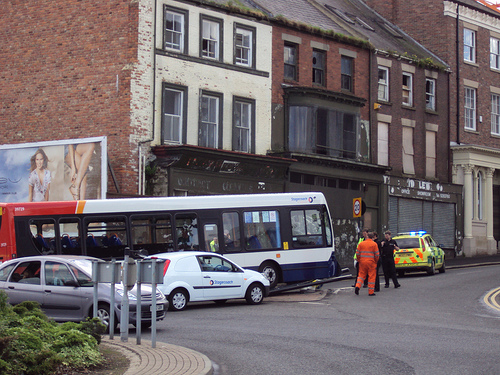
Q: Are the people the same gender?
A: No, they are both male and female.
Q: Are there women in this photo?
A: Yes, there is a woman.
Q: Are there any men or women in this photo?
A: Yes, there is a woman.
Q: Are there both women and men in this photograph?
A: Yes, there are both a woman and a man.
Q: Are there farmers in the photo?
A: No, there are no farmers.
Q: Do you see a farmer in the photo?
A: No, there are no farmers.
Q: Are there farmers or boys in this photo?
A: No, there are no farmers or boys.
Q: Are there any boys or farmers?
A: No, there are no farmers or boys.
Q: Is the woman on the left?
A: Yes, the woman is on the left of the image.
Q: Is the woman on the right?
A: No, the woman is on the left of the image.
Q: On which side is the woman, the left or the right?
A: The woman is on the left of the image.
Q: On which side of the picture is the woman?
A: The woman is on the left of the image.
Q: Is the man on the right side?
A: Yes, the man is on the right of the image.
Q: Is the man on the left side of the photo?
A: No, the man is on the right of the image.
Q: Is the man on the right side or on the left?
A: The man is on the right of the image.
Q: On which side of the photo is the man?
A: The man is on the right of the image.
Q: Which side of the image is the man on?
A: The man is on the right of the image.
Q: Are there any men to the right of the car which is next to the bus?
A: Yes, there is a man to the right of the car.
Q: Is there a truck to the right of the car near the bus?
A: No, there is a man to the right of the car.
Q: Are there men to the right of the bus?
A: Yes, there is a man to the right of the bus.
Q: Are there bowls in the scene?
A: No, there are no bowls.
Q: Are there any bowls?
A: No, there are no bowls.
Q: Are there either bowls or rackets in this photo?
A: No, there are no bowls or rackets.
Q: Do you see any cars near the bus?
A: Yes, there is a car near the bus.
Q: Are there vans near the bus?
A: No, there is a car near the bus.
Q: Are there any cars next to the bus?
A: Yes, there is a car next to the bus.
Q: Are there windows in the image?
A: Yes, there is a window.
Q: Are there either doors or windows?
A: Yes, there is a window.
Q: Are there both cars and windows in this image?
A: Yes, there are both a window and a car.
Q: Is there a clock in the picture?
A: No, there are no clocks.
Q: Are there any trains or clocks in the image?
A: No, there are no clocks or trains.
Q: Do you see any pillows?
A: No, there are no pillows.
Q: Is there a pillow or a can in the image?
A: No, there are no pillows or cans.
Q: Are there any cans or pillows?
A: No, there are no pillows or cans.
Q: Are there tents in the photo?
A: No, there are no tents.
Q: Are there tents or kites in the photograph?
A: No, there are no tents or kites.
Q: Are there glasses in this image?
A: No, there are no glasses.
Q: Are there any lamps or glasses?
A: No, there are no glasses or lamps.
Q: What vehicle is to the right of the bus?
A: The vehicle is a car.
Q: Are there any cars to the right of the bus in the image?
A: Yes, there is a car to the right of the bus.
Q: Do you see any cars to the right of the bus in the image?
A: Yes, there is a car to the right of the bus.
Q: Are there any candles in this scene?
A: No, there are no candles.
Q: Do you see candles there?
A: No, there are no candles.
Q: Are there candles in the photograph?
A: No, there are no candles.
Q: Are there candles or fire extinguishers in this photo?
A: No, there are no candles or fire extinguishers.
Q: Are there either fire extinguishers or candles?
A: No, there are no candles or fire extinguishers.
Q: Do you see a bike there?
A: No, there are no bikes.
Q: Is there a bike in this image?
A: No, there are no bikes.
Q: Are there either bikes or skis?
A: No, there are no bikes or skis.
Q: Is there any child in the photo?
A: No, there are no children.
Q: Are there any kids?
A: No, there are no kids.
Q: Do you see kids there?
A: No, there are no kids.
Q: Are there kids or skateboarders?
A: No, there are no kids or skateboarders.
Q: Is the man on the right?
A: Yes, the man is on the right of the image.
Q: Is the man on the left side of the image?
A: No, the man is on the right of the image.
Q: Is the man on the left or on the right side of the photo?
A: The man is on the right of the image.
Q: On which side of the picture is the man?
A: The man is on the right of the image.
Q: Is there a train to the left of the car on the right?
A: No, there is a man to the left of the car.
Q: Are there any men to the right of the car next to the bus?
A: Yes, there is a man to the right of the car.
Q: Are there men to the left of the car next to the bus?
A: No, the man is to the right of the car.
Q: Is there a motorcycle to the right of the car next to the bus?
A: No, there is a man to the right of the car.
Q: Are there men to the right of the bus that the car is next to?
A: Yes, there is a man to the right of the bus.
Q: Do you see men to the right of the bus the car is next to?
A: Yes, there is a man to the right of the bus.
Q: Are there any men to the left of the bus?
A: No, the man is to the right of the bus.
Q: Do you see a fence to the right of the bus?
A: No, there is a man to the right of the bus.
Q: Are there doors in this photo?
A: Yes, there is a door.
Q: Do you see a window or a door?
A: Yes, there is a door.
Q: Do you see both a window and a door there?
A: Yes, there are both a door and a window.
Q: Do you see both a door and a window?
A: Yes, there are both a door and a window.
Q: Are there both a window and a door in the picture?
A: Yes, there are both a door and a window.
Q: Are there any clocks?
A: No, there are no clocks.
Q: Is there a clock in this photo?
A: No, there are no clocks.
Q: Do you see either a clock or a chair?
A: No, there are no clocks or chairs.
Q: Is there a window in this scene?
A: Yes, there is a window.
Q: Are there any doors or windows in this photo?
A: Yes, there is a window.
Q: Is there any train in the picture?
A: No, there are no trains.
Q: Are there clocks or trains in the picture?
A: No, there are no trains or clocks.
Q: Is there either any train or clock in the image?
A: No, there are no trains or clocks.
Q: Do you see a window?
A: Yes, there is a window.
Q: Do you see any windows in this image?
A: Yes, there is a window.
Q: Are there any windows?
A: Yes, there is a window.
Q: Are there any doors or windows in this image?
A: Yes, there is a window.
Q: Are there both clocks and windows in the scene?
A: No, there is a window but no clocks.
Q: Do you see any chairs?
A: No, there are no chairs.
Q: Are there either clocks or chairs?
A: No, there are no chairs or clocks.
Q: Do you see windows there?
A: Yes, there are windows.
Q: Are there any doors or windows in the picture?
A: Yes, there are windows.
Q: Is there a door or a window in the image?
A: Yes, there are windows.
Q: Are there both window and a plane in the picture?
A: No, there are windows but no airplanes.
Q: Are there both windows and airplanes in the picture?
A: No, there are windows but no airplanes.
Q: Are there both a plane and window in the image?
A: No, there are windows but no airplanes.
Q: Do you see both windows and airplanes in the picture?
A: No, there are windows but no airplanes.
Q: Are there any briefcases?
A: No, there are no briefcases.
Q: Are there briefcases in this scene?
A: No, there are no briefcases.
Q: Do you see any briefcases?
A: No, there are no briefcases.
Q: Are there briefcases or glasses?
A: No, there are no briefcases or glasses.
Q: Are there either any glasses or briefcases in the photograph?
A: No, there are no briefcases or glasses.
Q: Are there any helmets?
A: No, there are no helmets.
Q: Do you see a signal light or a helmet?
A: No, there are no helmets or traffic lights.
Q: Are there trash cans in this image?
A: No, there are no trash cans.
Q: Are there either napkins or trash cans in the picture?
A: No, there are no trash cans or napkins.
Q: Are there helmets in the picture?
A: No, there are no helmets.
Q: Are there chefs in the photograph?
A: No, there are no chefs.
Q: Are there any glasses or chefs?
A: No, there are no chefs or glasses.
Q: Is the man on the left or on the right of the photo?
A: The man is on the right of the image.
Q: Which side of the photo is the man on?
A: The man is on the right of the image.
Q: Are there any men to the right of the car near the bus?
A: Yes, there is a man to the right of the car.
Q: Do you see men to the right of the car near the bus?
A: Yes, there is a man to the right of the car.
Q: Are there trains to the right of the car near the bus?
A: No, there is a man to the right of the car.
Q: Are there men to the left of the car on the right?
A: Yes, there is a man to the left of the car.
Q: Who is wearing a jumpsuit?
A: The man is wearing a jumpsuit.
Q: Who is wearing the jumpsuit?
A: The man is wearing a jumpsuit.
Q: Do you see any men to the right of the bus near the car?
A: Yes, there is a man to the right of the bus.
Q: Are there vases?
A: No, there are no vases.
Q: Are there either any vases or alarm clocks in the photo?
A: No, there are no vases or alarm clocks.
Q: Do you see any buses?
A: Yes, there is a bus.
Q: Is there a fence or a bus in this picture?
A: Yes, there is a bus.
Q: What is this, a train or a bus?
A: This is a bus.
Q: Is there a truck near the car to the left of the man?
A: No, there is a bus near the car.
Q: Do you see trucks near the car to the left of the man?
A: No, there is a bus near the car.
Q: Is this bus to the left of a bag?
A: No, the bus is to the left of a man.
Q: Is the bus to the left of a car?
A: Yes, the bus is to the left of a car.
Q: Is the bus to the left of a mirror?
A: No, the bus is to the left of a car.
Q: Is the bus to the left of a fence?
A: No, the bus is to the left of a man.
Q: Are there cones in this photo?
A: No, there are no cones.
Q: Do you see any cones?
A: No, there are no cones.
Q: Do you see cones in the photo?
A: No, there are no cones.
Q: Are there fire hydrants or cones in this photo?
A: No, there are no cones or fire hydrants.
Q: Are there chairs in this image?
A: No, there are no chairs.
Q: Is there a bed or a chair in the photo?
A: No, there are no chairs or beds.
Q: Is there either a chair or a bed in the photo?
A: No, there are no chairs or beds.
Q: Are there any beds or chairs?
A: No, there are no chairs or beds.